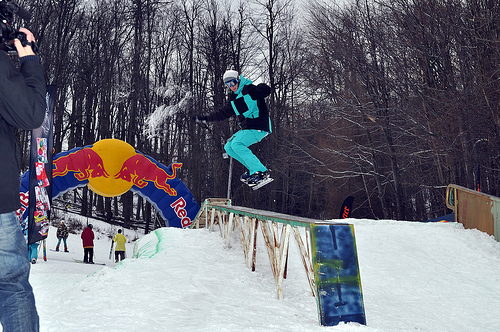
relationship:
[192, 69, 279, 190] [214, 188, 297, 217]
man above air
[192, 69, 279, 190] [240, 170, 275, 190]
man riding snowboard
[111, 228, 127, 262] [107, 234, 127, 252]
people wearing coat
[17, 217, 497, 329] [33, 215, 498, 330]
snow on ground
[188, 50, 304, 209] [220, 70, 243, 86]
man wearing a cap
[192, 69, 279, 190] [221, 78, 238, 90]
man wearing glasses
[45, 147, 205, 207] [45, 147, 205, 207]
balloon with balloon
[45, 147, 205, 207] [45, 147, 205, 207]
balloon on balloon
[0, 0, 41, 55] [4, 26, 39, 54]
camera in hand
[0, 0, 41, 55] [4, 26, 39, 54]
camera held by hand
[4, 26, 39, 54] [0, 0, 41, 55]
hand holds camera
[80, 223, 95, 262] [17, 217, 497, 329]
people in snow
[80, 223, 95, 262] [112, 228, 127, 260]
people in person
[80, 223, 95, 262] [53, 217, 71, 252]
people in person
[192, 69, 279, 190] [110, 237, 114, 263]
man on skis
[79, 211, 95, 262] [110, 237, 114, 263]
people on skis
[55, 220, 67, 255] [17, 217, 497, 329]
people standing in snow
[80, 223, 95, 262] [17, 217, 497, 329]
people standing in snow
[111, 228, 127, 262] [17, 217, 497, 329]
people standing in snow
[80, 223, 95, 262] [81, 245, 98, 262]
people wearing pants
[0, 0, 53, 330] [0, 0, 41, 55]
man holding camera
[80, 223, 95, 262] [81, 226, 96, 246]
people wearing coat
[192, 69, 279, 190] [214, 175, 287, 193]
man using snowboard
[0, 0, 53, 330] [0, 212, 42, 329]
man wearing jeans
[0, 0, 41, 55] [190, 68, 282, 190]
camera filming snowboarder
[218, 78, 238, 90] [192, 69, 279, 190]
glasses worn by man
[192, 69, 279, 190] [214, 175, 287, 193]
man riding snowboard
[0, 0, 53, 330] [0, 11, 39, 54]
man holding camera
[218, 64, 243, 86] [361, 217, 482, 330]
cap worn by snow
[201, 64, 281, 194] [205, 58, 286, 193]
suit worn by snowboarder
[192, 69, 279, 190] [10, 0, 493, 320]
man in air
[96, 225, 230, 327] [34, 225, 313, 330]
snow on ground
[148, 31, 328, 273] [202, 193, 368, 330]
skateboarder jumping barrier